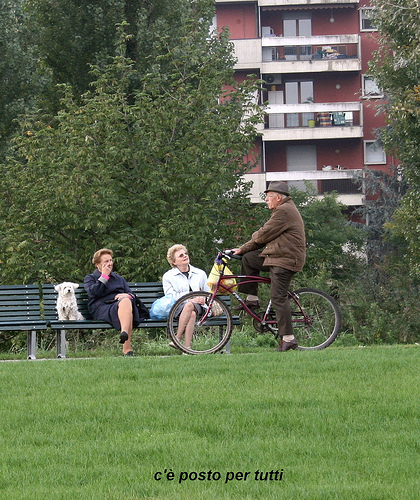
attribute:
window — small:
[358, 132, 395, 176]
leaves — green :
[87, 77, 97, 88]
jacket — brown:
[237, 197, 304, 272]